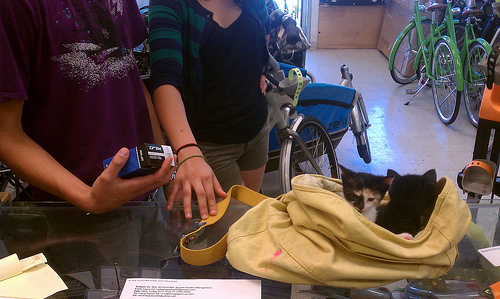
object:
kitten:
[336, 162, 395, 225]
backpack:
[177, 173, 474, 290]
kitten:
[376, 168, 442, 240]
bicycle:
[386, 0, 464, 126]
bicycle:
[412, 0, 498, 129]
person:
[0, 0, 180, 215]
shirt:
[0, 0, 154, 207]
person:
[143, 0, 281, 220]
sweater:
[145, 2, 215, 106]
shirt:
[148, 0, 273, 146]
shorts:
[186, 114, 275, 193]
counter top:
[0, 197, 500, 297]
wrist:
[175, 143, 206, 165]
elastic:
[175, 143, 202, 156]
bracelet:
[174, 154, 210, 172]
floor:
[264, 48, 500, 201]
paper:
[0, 249, 67, 298]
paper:
[118, 275, 264, 298]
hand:
[165, 157, 228, 221]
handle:
[178, 184, 285, 267]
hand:
[87, 146, 179, 215]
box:
[100, 143, 177, 181]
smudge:
[270, 245, 289, 259]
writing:
[132, 285, 214, 298]